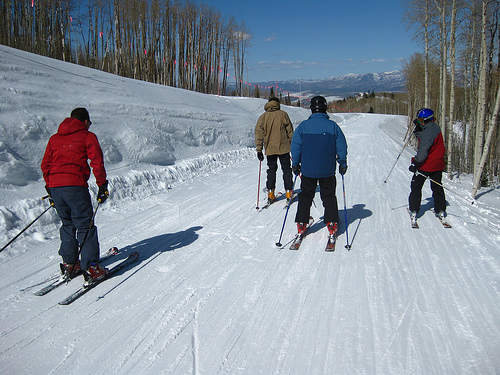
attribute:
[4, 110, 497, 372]
floor — white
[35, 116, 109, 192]
jacket — red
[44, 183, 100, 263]
pants — dark blue, black, blue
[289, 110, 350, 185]
jacket — blue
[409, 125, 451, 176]
jacket — grey, red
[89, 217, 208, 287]
shadow — man's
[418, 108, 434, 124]
helmet — blue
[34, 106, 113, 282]
person — holding, here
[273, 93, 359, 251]
person — here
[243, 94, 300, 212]
person — here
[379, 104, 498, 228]
person — here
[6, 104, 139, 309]
skier — here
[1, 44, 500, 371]
snow — dirty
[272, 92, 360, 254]
skier — here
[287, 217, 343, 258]
pair — skis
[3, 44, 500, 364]
ground — snow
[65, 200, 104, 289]
ski pole — sticking out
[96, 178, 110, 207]
glove — black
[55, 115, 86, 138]
hood — red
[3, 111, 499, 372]
ski course — here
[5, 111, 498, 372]
tracks — many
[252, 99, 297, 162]
jacket — brown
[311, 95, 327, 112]
helmet — black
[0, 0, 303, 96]
markers — red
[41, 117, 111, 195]
snow jacket — red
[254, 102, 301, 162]
coat — brown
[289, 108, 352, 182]
coat — blue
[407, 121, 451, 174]
coat — red